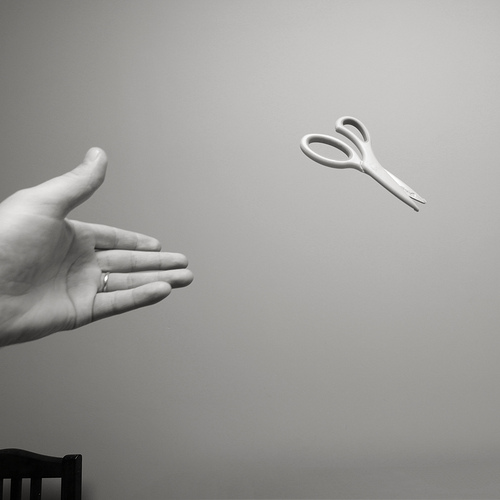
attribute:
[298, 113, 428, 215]
scissors — black, plastic, white, left handed, airborne, flying, slightly open, small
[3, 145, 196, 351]
hand — reaching, left hand, human, open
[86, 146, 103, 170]
nail — clean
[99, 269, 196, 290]
finger — ring finger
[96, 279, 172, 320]
finger — pinky finger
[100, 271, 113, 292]
ring — shiny, gold, wedding ring, metal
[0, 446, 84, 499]
chair — partially visible, wooden, dark brown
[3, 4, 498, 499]
wall — blank, bare, white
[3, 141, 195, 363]
person — left handed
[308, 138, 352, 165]
hole — largest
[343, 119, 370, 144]
hole — smallest